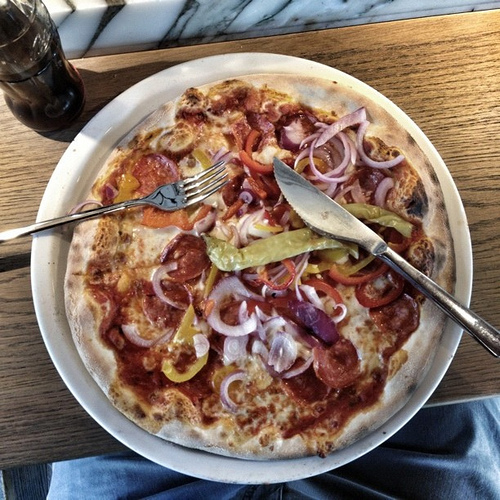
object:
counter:
[0, 9, 500, 469]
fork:
[0, 161, 229, 245]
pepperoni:
[162, 235, 209, 280]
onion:
[120, 102, 404, 409]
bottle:
[0, 1, 82, 136]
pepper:
[201, 203, 415, 271]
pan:
[28, 51, 474, 487]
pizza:
[62, 72, 457, 463]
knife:
[272, 157, 498, 356]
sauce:
[98, 324, 384, 436]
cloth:
[48, 397, 498, 499]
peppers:
[238, 129, 292, 196]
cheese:
[62, 74, 455, 461]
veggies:
[158, 106, 415, 414]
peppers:
[161, 296, 210, 384]